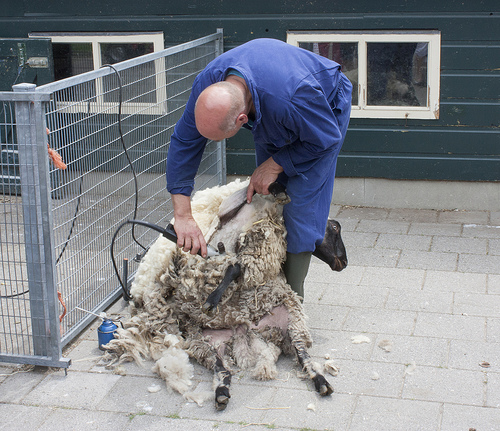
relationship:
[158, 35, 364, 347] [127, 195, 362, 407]
man holding sheep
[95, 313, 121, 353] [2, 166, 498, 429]
can on ground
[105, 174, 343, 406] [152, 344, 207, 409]
sheep has wool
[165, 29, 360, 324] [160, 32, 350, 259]
man in coat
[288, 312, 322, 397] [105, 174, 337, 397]
leg harvesting wool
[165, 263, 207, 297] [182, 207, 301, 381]
wool on sheep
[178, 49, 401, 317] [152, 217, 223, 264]
shearer holding electric shear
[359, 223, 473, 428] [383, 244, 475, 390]
ground paved with stones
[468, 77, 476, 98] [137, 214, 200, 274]
green building behind shearer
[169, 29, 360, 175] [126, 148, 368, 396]
man sheering sheep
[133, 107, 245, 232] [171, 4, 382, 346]
hand on man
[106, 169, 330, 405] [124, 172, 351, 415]
coat sheered off sheep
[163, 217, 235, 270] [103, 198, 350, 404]
buzzers shear sheep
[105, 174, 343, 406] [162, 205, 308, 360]
sheep on ground being shorn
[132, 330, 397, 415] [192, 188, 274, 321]
hooves of sheep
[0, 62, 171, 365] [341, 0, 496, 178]
metal fence on side of green building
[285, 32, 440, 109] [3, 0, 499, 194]
window on building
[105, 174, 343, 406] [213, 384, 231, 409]
sheep has hoof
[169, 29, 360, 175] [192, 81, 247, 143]
man has bald head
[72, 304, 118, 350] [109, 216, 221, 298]
oil to smooth buzzers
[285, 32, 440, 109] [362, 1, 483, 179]
window on a building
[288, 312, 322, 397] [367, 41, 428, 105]
leg in window glass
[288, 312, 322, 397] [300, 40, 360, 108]
leg in window glass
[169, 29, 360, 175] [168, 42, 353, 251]
man in a coat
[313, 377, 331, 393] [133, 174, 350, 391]
hoof of sheep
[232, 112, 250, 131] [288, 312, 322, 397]
ear of leg